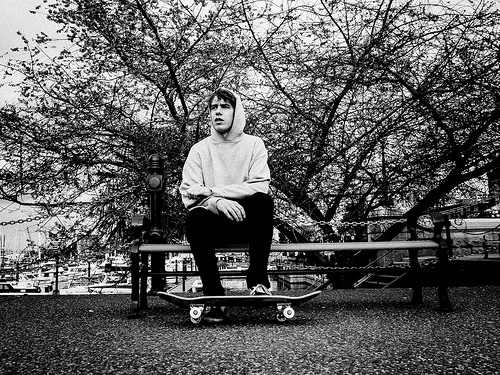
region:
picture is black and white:
[2, 1, 489, 366]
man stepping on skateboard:
[145, 271, 332, 330]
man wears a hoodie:
[175, 86, 279, 223]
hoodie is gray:
[169, 86, 281, 218]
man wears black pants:
[182, 192, 284, 299]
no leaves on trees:
[332, 2, 495, 210]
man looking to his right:
[177, 88, 291, 293]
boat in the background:
[6, 228, 136, 300]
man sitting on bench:
[117, 216, 456, 320]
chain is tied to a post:
[0, 152, 165, 299]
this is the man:
[175, 85, 268, 282]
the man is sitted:
[180, 85, 276, 291]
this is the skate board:
[160, 286, 315, 323]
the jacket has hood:
[235, 110, 245, 127]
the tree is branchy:
[319, 34, 461, 172]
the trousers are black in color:
[199, 227, 267, 270]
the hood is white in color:
[212, 142, 244, 192]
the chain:
[346, 218, 352, 231]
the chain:
[327, 220, 344, 240]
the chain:
[344, 204, 361, 264]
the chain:
[339, 218, 348, 236]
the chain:
[334, 213, 341, 239]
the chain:
[367, 211, 375, 242]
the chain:
[331, 203, 349, 250]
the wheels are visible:
[287, 304, 299, 322]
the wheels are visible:
[281, 303, 300, 331]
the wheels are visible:
[287, 311, 301, 326]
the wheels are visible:
[285, 308, 297, 339]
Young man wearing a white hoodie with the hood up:
[151, 82, 299, 231]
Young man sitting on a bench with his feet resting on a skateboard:
[164, 79, 296, 335]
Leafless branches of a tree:
[41, 8, 457, 93]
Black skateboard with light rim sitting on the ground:
[152, 287, 323, 317]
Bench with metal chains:
[299, 211, 453, 325]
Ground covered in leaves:
[310, 327, 487, 372]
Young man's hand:
[213, 197, 246, 222]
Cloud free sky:
[0, 0, 32, 30]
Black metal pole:
[136, 145, 168, 227]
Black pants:
[178, 194, 288, 290]